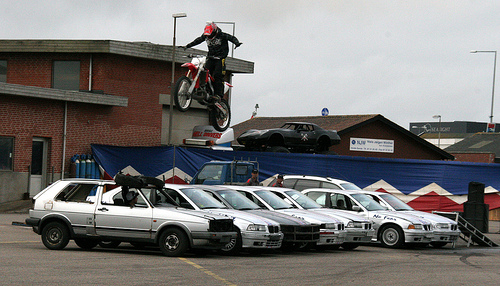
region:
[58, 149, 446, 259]
THE CAR ARE PARKED IN A LINE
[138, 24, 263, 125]
a bike is on top of the cars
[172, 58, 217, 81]
the bike is red in colour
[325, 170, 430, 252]
the cars are white in colour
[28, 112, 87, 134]
the house is brown in colour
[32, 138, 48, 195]
the door is closed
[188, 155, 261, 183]
the lorry is blue in colour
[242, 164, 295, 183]
people on the back of the truck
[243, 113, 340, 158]
a black car on the display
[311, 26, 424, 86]
the sky is cloudy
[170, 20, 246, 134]
man riding motorcycle in air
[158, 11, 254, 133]
man riding a dirt bike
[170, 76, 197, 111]
black wheel of dirt bike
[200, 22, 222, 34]
red helmet of dirt bike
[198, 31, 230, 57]
white and blue sweatshirt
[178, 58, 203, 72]
red front of bike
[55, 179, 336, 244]
line of parked cars on ground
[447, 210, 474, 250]
small black ramp by cars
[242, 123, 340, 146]
black car on platform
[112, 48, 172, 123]
red brick building in back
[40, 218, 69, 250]
A rear tire on a car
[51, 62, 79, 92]
A window on a building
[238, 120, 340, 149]
A black classic corvette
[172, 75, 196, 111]
Front tire on a dirt bike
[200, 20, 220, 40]
A motorcross helmet worn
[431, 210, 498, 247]
A ramp set up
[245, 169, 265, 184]
A security guard watching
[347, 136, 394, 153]
A sign on a building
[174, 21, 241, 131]
A motorcross stunt racer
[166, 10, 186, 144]
A light pole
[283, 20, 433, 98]
this is the sky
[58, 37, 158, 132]
this is a building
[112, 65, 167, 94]
this is the wall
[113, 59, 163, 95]
the wall is brown in color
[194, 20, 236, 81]
this is a man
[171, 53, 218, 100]
this is a motorbike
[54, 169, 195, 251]
this is a car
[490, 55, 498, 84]
this is a pole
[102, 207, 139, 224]
the car is white in color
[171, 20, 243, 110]
a person on a motorcycle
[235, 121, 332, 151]
a parked black car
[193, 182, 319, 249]
a parked black car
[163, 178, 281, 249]
a parked silver car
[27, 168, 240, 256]
a parked silver car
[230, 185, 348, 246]
a parked silver car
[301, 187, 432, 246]
a parked silver car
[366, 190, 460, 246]
a parked silver car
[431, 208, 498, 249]
A small stunt ramp